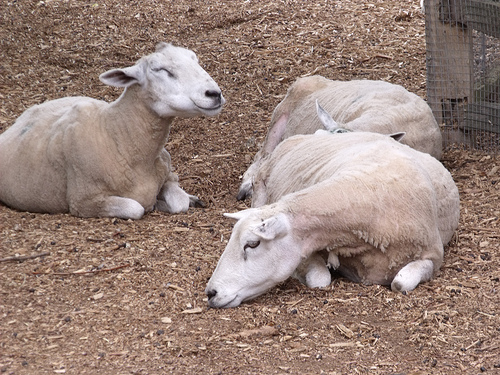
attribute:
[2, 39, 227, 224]
lamb — laying down, white, smilig, lying down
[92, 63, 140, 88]
ear — large, his, small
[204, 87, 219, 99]
nose — black, great, his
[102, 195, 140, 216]
leg — white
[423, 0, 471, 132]
wood — pieces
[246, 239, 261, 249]
eye — black, closed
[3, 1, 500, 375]
photo — in the summer, owned by zander zeke, taken with lens, artistic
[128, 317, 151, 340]
woodchip — small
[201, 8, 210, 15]
wood chip — small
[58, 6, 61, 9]
wood chip — small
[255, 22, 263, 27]
wood chip — small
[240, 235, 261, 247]
ee — his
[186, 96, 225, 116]
mouth — his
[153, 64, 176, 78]
eye — closed